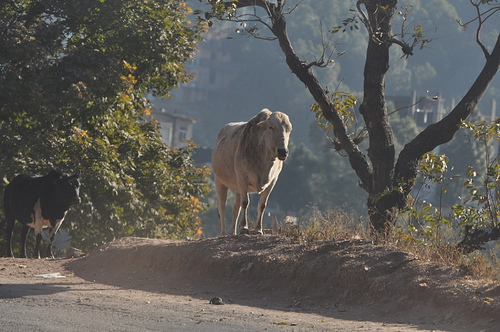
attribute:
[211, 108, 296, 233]
cow — dirt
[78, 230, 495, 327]
hill — small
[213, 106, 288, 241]
cow — white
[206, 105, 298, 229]
cow — standing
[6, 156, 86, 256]
cow — standing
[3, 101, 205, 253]
leaves — green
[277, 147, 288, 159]
nose — black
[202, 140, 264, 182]
fur — white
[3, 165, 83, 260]
cow — black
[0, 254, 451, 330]
sand — brown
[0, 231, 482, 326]
ground — sandy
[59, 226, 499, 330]
hill — dirt